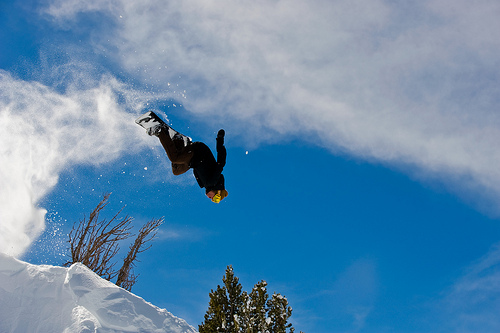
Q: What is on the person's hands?
A: Gloves.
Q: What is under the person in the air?
A: Snow.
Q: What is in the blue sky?
A: Clouds.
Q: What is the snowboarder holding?
A: The snowboard.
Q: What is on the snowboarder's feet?
A: Boots.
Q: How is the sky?
A: Blue and clear.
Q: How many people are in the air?
A: 1.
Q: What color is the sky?
A: Blue.